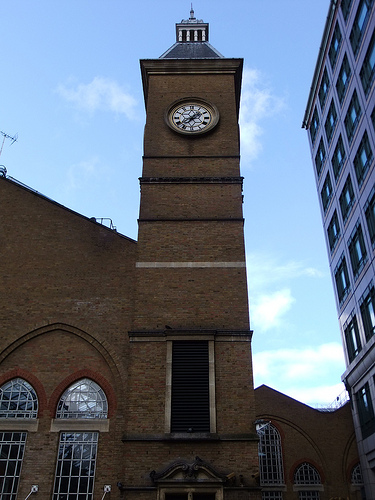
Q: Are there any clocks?
A: Yes, there is a clock.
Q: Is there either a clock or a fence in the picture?
A: Yes, there is a clock.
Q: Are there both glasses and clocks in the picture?
A: No, there is a clock but no glasses.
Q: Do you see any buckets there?
A: No, there are no buckets.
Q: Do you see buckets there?
A: No, there are no buckets.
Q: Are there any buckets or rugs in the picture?
A: No, there are no buckets or rugs.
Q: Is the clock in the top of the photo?
A: Yes, the clock is in the top of the image.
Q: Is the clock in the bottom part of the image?
A: No, the clock is in the top of the image.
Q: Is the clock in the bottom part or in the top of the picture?
A: The clock is in the top of the image.